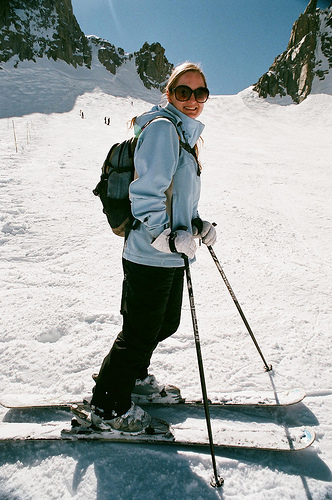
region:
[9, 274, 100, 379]
the snow is white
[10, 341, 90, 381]
the snow is on ground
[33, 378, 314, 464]
feet on the skis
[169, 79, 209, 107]
the shades are black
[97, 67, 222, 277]
woman wearing the backpack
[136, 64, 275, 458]
woman holding ski poles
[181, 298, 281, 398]
ski poles are black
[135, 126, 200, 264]
the jacket is blue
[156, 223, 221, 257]
the gloves are white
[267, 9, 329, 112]
snow on the mountains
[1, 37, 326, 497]
A woman skiing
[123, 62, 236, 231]
A woman wearing sunglasses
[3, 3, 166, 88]
Snowy mountain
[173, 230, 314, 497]
Black ski poles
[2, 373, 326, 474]
A pair of snow covered skis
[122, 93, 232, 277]
A light blue hooded ski jacket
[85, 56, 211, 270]
A woman wearing a backpack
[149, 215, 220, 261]
A pair of white gloves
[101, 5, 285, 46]
A clear blue sky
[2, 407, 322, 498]
A skiers shadow on the snow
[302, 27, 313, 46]
slopes of a mountain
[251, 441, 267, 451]
section of skate board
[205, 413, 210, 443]
part of an ice skating stick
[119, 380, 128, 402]
foot of a lady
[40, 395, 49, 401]
back part of a skate board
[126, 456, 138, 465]
section of a snowy landscape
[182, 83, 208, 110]
face of a lady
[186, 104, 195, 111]
mouth of a lady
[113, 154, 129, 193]
part of a bag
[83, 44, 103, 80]
section of a snowy mountain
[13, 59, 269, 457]
lady standing on skis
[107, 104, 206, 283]
blue ski jacket on lady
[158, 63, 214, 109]
lady wearing big sunglasses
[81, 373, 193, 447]
snow covered snow boots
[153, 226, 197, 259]
white snow gloves on lady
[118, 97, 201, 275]
blue snow jacket on girl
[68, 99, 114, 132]
skiers in distance on mountain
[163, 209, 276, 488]
lady holding two ski poles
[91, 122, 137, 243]
blue and black backpack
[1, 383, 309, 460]
white snow covered skis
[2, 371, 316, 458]
A pair of skis being worn.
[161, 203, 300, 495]
She is holding ski poles.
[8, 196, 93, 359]
The snow is thick.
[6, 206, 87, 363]
The snow reflects a lot of light.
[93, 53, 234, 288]
She is wearing sun glasses.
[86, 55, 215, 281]
She is wearing blue.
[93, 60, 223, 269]
She is wearing a backpack.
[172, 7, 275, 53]
The sky is clear and blue.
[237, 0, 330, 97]
Mountains are in the background.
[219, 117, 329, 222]
A lot of snow is on the ground.